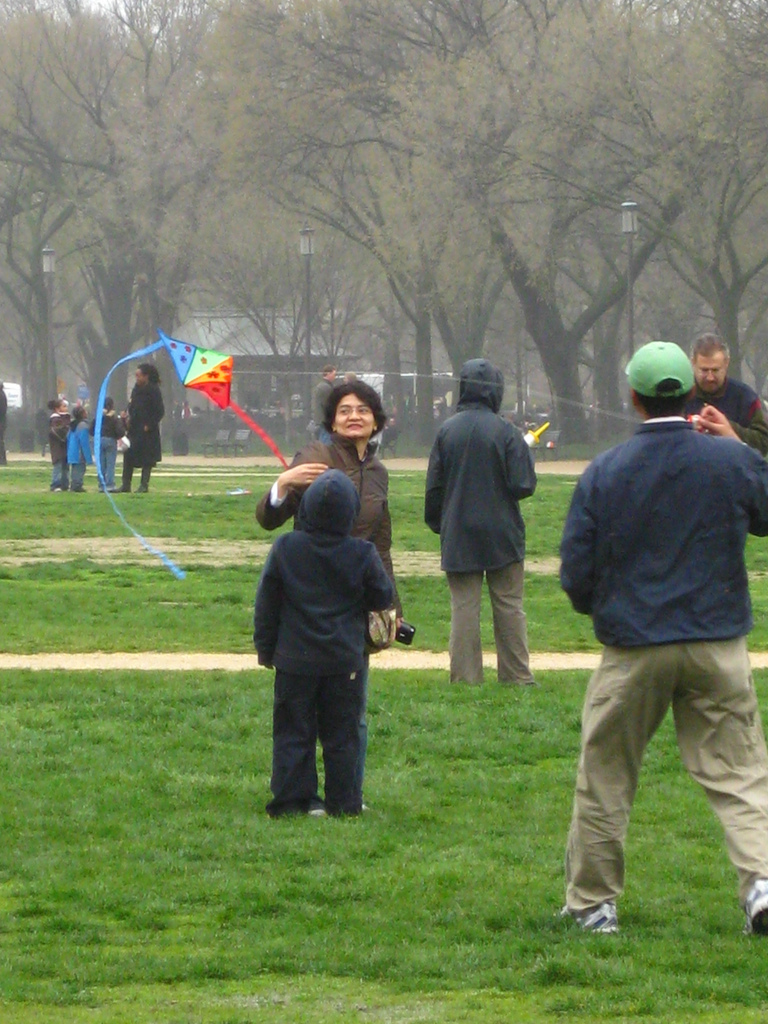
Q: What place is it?
A: It is a park.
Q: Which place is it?
A: It is a park.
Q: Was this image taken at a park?
A: Yes, it was taken in a park.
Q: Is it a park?
A: Yes, it is a park.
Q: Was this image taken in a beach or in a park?
A: It was taken at a park.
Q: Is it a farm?
A: No, it is a park.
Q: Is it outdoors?
A: Yes, it is outdoors.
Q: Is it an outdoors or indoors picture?
A: It is outdoors.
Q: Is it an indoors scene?
A: No, it is outdoors.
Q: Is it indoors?
A: No, it is outdoors.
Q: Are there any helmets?
A: No, there are no helmets.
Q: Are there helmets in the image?
A: No, there are no helmets.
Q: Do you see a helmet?
A: No, there are no helmets.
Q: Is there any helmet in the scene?
A: No, there are no helmets.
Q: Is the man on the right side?
A: Yes, the man is on the right of the image.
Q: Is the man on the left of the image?
A: No, the man is on the right of the image.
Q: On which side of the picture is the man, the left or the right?
A: The man is on the right of the image.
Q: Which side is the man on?
A: The man is on the right of the image.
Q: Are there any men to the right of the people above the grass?
A: Yes, there is a man to the right of the people.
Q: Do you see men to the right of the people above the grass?
A: Yes, there is a man to the right of the people.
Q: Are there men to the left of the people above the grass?
A: No, the man is to the right of the people.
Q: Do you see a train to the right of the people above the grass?
A: No, there is a man to the right of the people.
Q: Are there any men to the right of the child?
A: Yes, there is a man to the right of the child.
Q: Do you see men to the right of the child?
A: Yes, there is a man to the right of the child.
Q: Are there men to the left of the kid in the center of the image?
A: No, the man is to the right of the child.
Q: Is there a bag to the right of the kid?
A: No, there is a man to the right of the kid.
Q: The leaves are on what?
A: The leaves are on the tree.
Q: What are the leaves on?
A: The leaves are on the tree.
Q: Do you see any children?
A: Yes, there is a child.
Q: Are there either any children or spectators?
A: Yes, there is a child.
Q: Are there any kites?
A: Yes, there is a kite.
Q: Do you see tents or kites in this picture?
A: Yes, there is a kite.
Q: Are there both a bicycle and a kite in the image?
A: No, there is a kite but no bicycles.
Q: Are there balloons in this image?
A: No, there are no balloons.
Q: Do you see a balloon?
A: No, there are no balloons.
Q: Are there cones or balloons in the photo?
A: No, there are no balloons or cones.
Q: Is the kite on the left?
A: Yes, the kite is on the left of the image.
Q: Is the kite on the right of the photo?
A: No, the kite is on the left of the image.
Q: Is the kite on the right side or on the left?
A: The kite is on the left of the image.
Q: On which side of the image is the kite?
A: The kite is on the left of the image.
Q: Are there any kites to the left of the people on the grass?
A: Yes, there is a kite to the left of the people.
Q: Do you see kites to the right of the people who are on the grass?
A: No, the kite is to the left of the people.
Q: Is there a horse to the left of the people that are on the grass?
A: No, there is a kite to the left of the people.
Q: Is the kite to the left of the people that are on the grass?
A: Yes, the kite is to the left of the people.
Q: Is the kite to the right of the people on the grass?
A: No, the kite is to the left of the people.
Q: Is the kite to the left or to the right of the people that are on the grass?
A: The kite is to the left of the people.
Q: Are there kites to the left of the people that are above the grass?
A: Yes, there is a kite to the left of the people.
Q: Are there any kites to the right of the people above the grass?
A: No, the kite is to the left of the people.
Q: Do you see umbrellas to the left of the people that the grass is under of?
A: No, there is a kite to the left of the people.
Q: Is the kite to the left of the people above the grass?
A: Yes, the kite is to the left of the people.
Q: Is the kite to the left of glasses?
A: No, the kite is to the left of the people.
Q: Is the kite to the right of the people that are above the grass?
A: No, the kite is to the left of the people.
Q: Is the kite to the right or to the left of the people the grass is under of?
A: The kite is to the left of the people.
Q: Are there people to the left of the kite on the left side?
A: No, the people are to the right of the kite.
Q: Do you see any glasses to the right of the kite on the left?
A: No, there are people to the right of the kite.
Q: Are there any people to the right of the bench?
A: Yes, there are people to the right of the bench.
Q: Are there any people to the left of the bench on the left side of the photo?
A: No, the people are to the right of the bench.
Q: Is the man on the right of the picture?
A: Yes, the man is on the right of the image.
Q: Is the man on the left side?
A: No, the man is on the right of the image.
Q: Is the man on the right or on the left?
A: The man is on the right of the image.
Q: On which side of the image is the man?
A: The man is on the right of the image.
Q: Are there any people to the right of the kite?
A: Yes, there are people to the right of the kite.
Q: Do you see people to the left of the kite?
A: No, the people are to the right of the kite.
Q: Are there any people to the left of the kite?
A: No, the people are to the right of the kite.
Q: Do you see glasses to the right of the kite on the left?
A: No, there are people to the right of the kite.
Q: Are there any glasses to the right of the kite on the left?
A: No, there are people to the right of the kite.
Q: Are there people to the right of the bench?
A: Yes, there are people to the right of the bench.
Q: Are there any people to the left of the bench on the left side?
A: No, the people are to the right of the bench.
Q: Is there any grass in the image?
A: Yes, there is grass.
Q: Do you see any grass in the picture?
A: Yes, there is grass.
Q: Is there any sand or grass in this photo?
A: Yes, there is grass.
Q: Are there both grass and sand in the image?
A: No, there is grass but no sand.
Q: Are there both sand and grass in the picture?
A: No, there is grass but no sand.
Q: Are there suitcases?
A: No, there are no suitcases.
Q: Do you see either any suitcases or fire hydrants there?
A: No, there are no suitcases or fire hydrants.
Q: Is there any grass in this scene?
A: Yes, there is grass.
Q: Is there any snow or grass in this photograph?
A: Yes, there is grass.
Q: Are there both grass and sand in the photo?
A: No, there is grass but no sand.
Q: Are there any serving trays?
A: No, there are no serving trays.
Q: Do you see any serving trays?
A: No, there are no serving trays.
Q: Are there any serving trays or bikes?
A: No, there are no serving trays or bikes.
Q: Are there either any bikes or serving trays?
A: No, there are no serving trays or bikes.